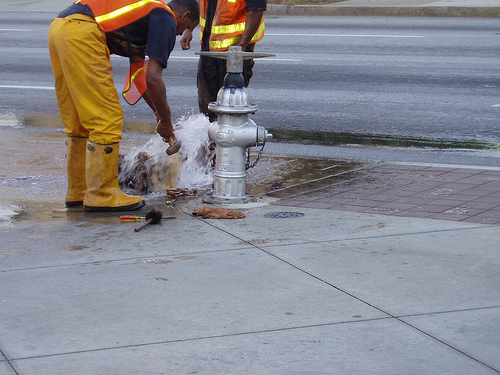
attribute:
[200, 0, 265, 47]
vest — orange, Bright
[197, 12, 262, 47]
stripes — yellow 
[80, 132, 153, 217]
boot — yellow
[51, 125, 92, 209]
boot — yellow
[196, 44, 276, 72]
handle — Gray 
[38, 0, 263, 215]
hydrant — fire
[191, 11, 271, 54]
stripes — Yellow 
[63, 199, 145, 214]
soles — black 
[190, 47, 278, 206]
hydrant — fire, silver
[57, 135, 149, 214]
boots — Yellow, rubber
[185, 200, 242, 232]
glove — Rubber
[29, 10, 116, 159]
pants — yellow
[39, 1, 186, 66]
shirt — blue 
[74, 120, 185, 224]
boots — Yellow , rubber 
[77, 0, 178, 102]
vest — orange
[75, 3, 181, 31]
outfit — orange, yellow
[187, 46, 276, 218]
fire hydrant — silver